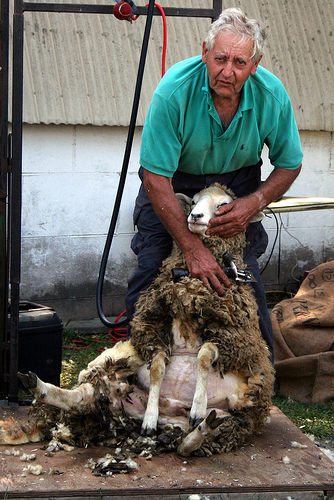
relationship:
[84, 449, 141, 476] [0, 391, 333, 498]
fur on table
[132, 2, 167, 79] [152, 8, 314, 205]
wire behind man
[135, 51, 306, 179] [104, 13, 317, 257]
shirt on man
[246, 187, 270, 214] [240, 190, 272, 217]
light spot on wrist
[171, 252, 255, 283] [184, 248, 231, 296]
razor in hand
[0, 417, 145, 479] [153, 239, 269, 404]
hair from sheep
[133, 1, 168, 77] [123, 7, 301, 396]
wire behind man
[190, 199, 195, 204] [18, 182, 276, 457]
eye of sheep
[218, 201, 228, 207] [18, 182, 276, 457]
eye of sheep